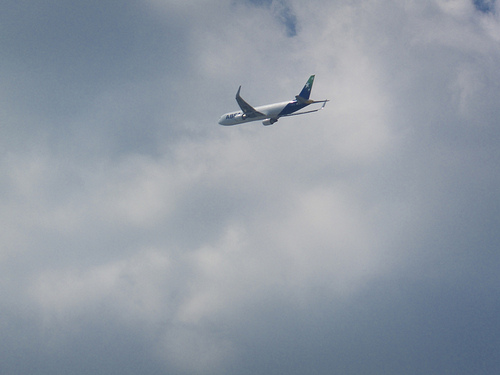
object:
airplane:
[218, 73, 330, 126]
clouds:
[0, 0, 97, 103]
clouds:
[11, 300, 48, 352]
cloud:
[319, 227, 473, 337]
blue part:
[269, 12, 329, 50]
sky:
[84, 57, 119, 77]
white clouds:
[187, 302, 233, 320]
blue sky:
[469, 1, 491, 13]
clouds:
[186, 127, 328, 237]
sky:
[449, 359, 479, 369]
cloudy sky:
[89, 194, 142, 217]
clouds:
[163, 293, 197, 352]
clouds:
[463, 42, 483, 150]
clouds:
[342, 49, 467, 203]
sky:
[201, 3, 227, 48]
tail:
[296, 70, 316, 105]